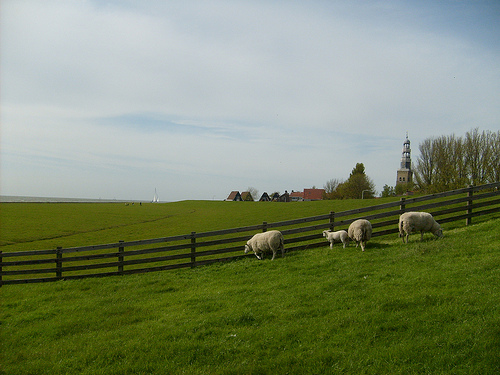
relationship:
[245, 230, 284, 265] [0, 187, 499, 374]
sheep on hill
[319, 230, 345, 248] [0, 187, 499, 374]
sheep on hill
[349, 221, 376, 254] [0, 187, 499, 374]
sheep on hill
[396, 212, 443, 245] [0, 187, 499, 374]
sheep on hill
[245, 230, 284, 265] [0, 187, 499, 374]
sheep eating grass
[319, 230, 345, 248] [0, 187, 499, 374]
sheep eating grass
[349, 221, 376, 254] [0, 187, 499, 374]
sheep eating grass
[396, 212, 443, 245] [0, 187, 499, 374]
sheep eating grass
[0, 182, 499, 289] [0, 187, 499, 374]
fence on hill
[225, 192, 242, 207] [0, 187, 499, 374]
house next to field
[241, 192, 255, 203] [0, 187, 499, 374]
house next to field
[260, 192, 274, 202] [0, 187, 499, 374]
house next to field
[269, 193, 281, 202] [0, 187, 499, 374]
house next to field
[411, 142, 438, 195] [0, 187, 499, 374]
trees by field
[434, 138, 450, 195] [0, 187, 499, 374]
tree by field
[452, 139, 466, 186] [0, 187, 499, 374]
tree by field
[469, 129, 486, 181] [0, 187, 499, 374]
tree by field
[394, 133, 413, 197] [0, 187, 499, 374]
building by field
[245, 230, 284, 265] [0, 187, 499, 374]
sheep walking on hill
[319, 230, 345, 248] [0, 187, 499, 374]
sheep walking on hill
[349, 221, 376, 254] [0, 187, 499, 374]
sheep walking on hill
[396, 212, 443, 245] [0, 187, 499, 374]
sheep walking on hill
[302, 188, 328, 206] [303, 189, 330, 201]
building with roof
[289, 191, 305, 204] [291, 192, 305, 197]
building with roof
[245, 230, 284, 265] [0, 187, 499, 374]
sheep grazzing on grass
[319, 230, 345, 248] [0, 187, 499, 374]
sheep grazzing on grass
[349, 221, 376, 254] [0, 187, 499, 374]
sheep grazzing on grass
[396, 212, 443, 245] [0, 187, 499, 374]
sheep grazzing on grass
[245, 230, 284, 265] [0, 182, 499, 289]
sheep grazing next to fence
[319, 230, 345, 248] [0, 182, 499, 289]
sheep grazing next to fence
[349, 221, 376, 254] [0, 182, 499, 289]
sheep grazing next to fence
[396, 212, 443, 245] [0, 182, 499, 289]
sheep grazing next to fence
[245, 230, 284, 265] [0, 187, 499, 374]
sheep graze in field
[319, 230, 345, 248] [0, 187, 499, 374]
sheep graze in field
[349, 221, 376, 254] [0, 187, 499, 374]
sheep graze in field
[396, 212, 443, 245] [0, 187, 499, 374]
sheep graze in field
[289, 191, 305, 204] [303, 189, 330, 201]
building with roof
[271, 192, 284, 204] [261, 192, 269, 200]
building with roof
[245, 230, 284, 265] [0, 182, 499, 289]
sheep by fence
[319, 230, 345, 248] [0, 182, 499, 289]
sheep by fence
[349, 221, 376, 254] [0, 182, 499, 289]
sheep by fence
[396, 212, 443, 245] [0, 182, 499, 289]
sheep by fence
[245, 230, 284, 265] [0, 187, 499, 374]
sheep grazing on grass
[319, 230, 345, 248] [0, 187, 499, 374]
sheep grazing on grass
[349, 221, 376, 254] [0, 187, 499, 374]
sheep grazing on grass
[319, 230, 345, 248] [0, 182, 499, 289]
sheep next to fence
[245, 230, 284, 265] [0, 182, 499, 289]
sheep next to fence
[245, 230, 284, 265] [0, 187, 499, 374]
sheep in field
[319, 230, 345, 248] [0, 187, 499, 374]
sheep in field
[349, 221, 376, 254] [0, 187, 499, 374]
sheep in field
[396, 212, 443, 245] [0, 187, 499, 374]
sheep in field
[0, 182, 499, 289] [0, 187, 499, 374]
fence in field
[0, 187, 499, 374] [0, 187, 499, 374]
grass in field